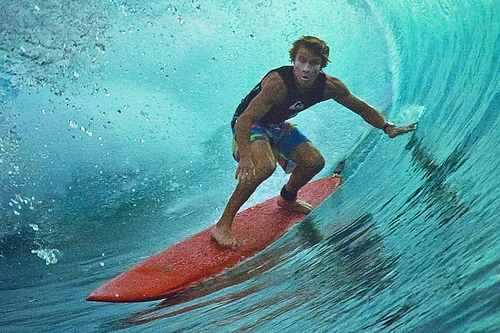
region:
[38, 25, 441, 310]
A man riding a wave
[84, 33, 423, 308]
A man on a red surfboard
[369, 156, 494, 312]
Blue ocean water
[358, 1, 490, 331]
A blue wave in the ocean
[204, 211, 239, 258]
A man's right foot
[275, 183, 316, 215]
A man's left foot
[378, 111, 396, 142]
A watch on a man's left hand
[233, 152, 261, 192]
A man's right hand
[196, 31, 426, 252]
A man wearing a blue sleeveless shirt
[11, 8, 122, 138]
Ocean spray from a large wave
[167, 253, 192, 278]
The top of a surf board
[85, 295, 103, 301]
The tip of a surf board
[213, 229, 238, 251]
Foot on surf board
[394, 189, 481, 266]
A curving blue wave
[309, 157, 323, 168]
A bent left knee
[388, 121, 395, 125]
A watch in the wrist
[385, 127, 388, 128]
A black watch strap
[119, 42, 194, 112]
Glassy like blue water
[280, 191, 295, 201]
A black ankle band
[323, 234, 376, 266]
Shadow of surfer on the wave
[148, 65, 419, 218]
The man is on the surfboard.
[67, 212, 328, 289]
The surfboard is red.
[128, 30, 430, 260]
The man is riding the wave.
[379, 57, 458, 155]
The man hand is touching the wave.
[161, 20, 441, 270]
The man is in the water.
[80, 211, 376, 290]
The surfboard is on top of the wave.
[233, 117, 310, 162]
The man is wearing swim trunks.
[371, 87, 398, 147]
The man is wearing a watch.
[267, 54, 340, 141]
The man is wearing a black shirt.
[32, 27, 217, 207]
Water splashing from the wave.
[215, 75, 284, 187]
arm of a person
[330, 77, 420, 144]
arm of a person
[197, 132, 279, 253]
leg of a person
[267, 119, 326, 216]
leg of a person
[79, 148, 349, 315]
red surfboard in the water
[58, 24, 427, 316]
person on a surfboard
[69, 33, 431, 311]
person riding a surfboard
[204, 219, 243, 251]
foot of a person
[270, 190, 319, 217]
foot of a person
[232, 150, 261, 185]
hand of a person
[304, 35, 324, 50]
Blonde hair on mans head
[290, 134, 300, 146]
Man wearing blue shorts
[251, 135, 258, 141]
Green on mans shorts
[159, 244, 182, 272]
red board under man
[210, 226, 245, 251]
mans bare feet on board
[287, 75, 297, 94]
man wearing black shirt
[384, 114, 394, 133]
watch on mans arm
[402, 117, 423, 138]
tip of mans hand in water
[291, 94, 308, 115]
black and white design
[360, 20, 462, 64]
wave surrounding man in water